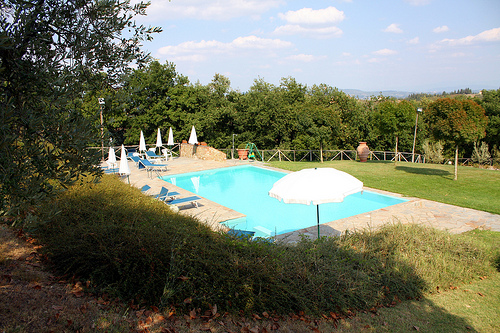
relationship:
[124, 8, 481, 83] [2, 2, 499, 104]
clouds in sky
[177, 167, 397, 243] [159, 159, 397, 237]
water in pool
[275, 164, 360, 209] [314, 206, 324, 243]
umbrella on pole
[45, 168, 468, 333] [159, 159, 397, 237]
bushes around pool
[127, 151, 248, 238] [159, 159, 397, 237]
chairs by pool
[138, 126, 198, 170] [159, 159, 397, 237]
umbrellas by pool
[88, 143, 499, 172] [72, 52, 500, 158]
fencing in front of trees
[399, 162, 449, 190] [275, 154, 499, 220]
shadows on grass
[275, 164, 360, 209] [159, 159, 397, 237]
umbrella outside pool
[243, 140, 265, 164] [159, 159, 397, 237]
swing set near pool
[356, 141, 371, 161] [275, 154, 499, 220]
vase on grass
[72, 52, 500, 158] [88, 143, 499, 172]
trees outside fencing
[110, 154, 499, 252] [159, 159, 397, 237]
patio outside pool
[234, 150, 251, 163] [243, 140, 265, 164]
plant pot near swing set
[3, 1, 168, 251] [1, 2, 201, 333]
tree on side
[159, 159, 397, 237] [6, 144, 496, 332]
pool in a backyard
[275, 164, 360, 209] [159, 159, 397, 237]
umbrella near a pool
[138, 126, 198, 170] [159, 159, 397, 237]
umbrellas by a pool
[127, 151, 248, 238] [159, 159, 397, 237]
chairs by a pool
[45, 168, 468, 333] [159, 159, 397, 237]
bushes near a pool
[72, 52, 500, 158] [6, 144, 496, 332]
trees beyond backyard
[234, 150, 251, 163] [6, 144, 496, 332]
plant pot in backyard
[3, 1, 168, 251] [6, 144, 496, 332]
tree in backyard